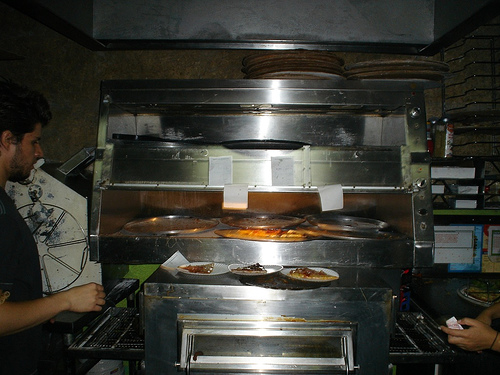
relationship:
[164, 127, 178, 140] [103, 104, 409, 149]
spice on top of shelf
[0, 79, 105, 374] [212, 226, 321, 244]
man looking at pizza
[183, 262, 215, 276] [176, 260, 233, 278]
food on top of a plate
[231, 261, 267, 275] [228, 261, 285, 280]
food on top of plate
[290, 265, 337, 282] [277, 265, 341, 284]
pizza on top of plate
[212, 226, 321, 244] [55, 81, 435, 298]
pizza inside oven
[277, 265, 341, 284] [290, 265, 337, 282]
plate filled with pizza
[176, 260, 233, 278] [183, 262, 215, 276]
plate filled with food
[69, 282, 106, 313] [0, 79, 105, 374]
hand of a man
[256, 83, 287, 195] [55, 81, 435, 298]
light reflected on oven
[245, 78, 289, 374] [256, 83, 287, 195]
reflection of light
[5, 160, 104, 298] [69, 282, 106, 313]
paper held in hand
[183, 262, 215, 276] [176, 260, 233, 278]
food on top of plate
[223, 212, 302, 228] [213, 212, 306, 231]
pizza on top of pan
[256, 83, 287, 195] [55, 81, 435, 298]
light running down oven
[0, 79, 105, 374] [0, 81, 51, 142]
man has hair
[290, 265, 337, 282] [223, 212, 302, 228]
single slice sitting blow whole pie